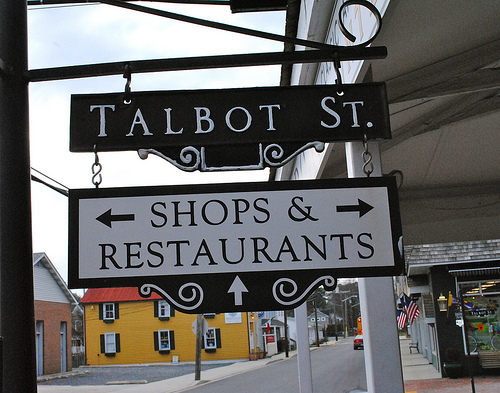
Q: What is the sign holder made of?
A: It is made of wrought iron.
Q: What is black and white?
A: The street sign is black and white.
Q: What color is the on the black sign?
A: The writing is white.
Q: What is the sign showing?
A: The sign is showing arrows directing to the shops and restaurants.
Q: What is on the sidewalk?
A: There is a bench on the sidewalk.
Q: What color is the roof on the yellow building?
A: The roof on the yellow building is red.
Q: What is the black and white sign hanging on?
A: The black and white sign is hanging on a pole.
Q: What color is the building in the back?
A: Yellow.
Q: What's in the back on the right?
A: American Flags.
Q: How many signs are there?
A: Two.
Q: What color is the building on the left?
A: White.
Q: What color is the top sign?
A: Black.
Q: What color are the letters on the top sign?
A: White.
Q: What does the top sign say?
A: Talbot St.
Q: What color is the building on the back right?
A: Black.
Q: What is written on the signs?
A: Shops and restaurants.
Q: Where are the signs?
A: Street.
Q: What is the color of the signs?
A: White and black.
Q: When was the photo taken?
A: Bright day.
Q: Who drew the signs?
A: Artist.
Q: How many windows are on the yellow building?
A: Six.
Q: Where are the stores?
A: Side of street.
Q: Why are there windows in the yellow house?
A: For light.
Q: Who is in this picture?
A: No one.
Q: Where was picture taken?
A: Talbot St.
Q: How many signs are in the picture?
A: 2.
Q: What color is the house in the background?
A: Yellow.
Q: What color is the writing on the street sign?
A: White.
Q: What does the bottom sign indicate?
A: Restaurants.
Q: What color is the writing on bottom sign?
A: Black.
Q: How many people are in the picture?
A: None.